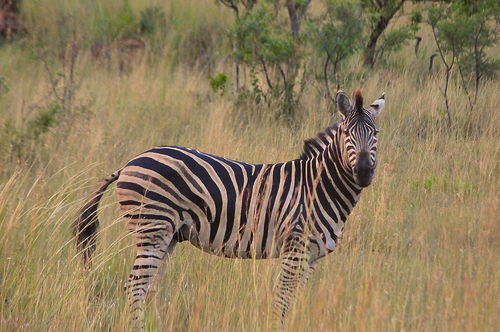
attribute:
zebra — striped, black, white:
[66, 80, 398, 331]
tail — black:
[65, 163, 127, 266]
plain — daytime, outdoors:
[1, 3, 499, 326]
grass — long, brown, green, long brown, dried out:
[1, 41, 496, 326]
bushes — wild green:
[4, 7, 492, 98]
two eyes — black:
[339, 126, 384, 139]